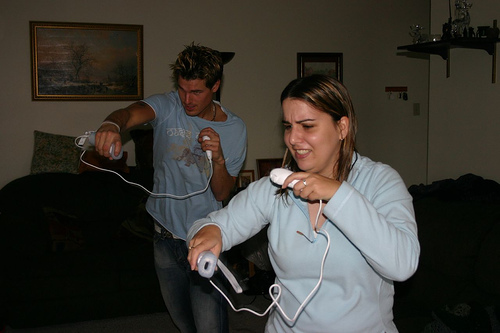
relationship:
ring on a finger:
[186, 246, 193, 248] [188, 237, 193, 261]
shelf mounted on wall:
[392, 1, 496, 82] [6, 5, 424, 169]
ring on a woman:
[300, 181, 309, 185] [185, 73, 421, 331]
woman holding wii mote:
[185, 73, 421, 331] [185, 166, 330, 321]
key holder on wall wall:
[379, 80, 414, 106] [6, 5, 424, 169]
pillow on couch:
[24, 134, 124, 192] [31, 144, 198, 246]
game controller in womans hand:
[197, 167, 330, 324] [190, 223, 222, 270]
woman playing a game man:
[185, 73, 421, 331] [72, 50, 237, 327]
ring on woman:
[300, 181, 309, 185] [160, 58, 445, 318]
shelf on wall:
[392, 1, 496, 82] [2, 5, 496, 181]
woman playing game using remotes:
[185, 73, 421, 331] [198, 163, 305, 289]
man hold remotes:
[91, 33, 254, 333] [58, 127, 126, 177]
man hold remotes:
[91, 33, 254, 333] [182, 126, 226, 189]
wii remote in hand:
[188, 240, 240, 304] [185, 224, 222, 269]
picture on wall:
[35, 24, 146, 97] [6, 5, 424, 169]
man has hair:
[91, 33, 254, 318] [171, 41, 225, 88]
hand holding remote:
[277, 167, 329, 208] [185, 245, 220, 279]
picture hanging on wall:
[35, 24, 146, 97] [235, 3, 293, 67]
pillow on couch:
[24, 134, 124, 192] [3, 167, 250, 332]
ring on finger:
[300, 181, 309, 185] [293, 180, 306, 194]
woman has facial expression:
[185, 73, 421, 331] [284, 100, 334, 169]